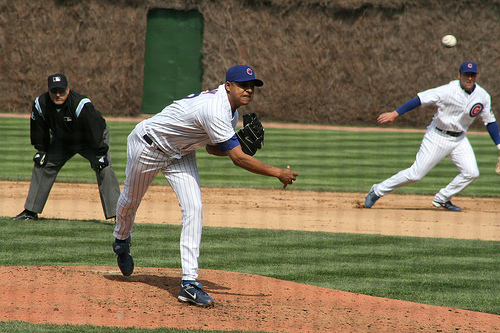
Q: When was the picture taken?
A: Daytime.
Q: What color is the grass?
A: Green.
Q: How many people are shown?
A: Three.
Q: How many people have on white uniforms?
A: Two.